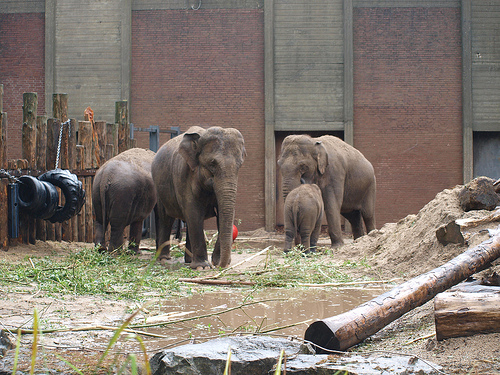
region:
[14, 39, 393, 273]
several elephants at a zoo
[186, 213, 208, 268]
the leg of an elephant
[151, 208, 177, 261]
the leg of an elephant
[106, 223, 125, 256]
the leg of an elephant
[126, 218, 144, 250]
the leg of an elephant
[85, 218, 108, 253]
the leg of an elephant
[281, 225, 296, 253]
the leg of an elephant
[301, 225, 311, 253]
the leg of an elephant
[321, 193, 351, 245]
the leg of an elephant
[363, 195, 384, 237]
the leg of an elephant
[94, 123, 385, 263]
four elephants standing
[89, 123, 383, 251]
the elephants are brown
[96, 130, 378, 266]
three large elephants stand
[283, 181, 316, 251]
one small elephants stands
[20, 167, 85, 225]
tires hang from rope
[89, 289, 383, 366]
the ground is wet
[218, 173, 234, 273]
the elephant has long trunk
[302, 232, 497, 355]
the trees are on the ground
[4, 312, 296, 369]
the grass is long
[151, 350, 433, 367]
the rock is wet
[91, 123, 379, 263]
four elephants standing together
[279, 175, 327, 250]
one baby elephant next to an adult elephant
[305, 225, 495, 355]
long brown log sitting in the enclosure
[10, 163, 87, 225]
three black rubber tires for elephants to play with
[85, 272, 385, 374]
muddy puddle of water in the middle of the enclosure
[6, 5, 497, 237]
brick building in the background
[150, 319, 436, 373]
two large rocks on the ground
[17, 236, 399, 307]
patchy bits of grass on the ground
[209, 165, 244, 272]
long elephant trunk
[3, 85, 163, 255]
wooden fence made of wood posts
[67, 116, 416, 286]
Four elephants hanging around a building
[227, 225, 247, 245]
A small red object by the elephant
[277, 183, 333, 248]
A very young elephant by the older elephants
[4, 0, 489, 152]
A red brick building behind the elephants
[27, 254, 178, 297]
Sparse green plant matter on the ground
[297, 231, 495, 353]
A thick brown log on the ground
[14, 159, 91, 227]
Thick black tires hanging on a rope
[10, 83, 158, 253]
A fence made of logs by the elephants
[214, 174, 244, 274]
The elephant's trunk is touching the ground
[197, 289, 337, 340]
A pool of brown water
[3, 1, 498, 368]
The elephant enclosure at the zoo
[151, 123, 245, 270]
A large brown and black elephant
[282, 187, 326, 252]
The behind of a baby elephant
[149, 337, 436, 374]
Two large wet rocks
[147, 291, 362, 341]
A stagnant puddle of brown water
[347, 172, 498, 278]
A mound of sand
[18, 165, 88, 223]
Three large black tires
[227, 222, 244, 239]
A large red ball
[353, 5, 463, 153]
A red and black brick wall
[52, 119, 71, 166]
a heavy metal chain